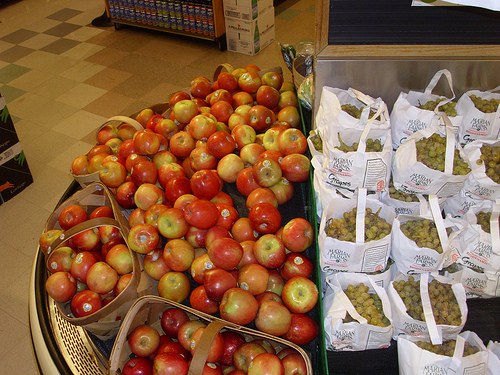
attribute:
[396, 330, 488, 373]
bag — white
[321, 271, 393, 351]
bag — white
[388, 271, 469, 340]
bag — white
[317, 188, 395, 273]
bag — white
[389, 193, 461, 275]
bag — white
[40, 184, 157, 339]
basket — woven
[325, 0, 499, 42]
display board — Black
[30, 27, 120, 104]
tile floor — Checkered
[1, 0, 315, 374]
tile — square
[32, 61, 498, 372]
display — mixed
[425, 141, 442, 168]
grapes — green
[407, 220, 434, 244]
grapes — green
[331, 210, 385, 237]
grapes — green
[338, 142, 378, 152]
grapes — green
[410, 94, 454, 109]
grapes — green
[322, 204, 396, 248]
grapes — Green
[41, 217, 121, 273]
handle — wooden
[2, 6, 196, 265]
tiled floor — multi colored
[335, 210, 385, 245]
grapes — green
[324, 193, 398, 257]
bag — white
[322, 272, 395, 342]
bag — white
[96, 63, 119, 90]
tile — square